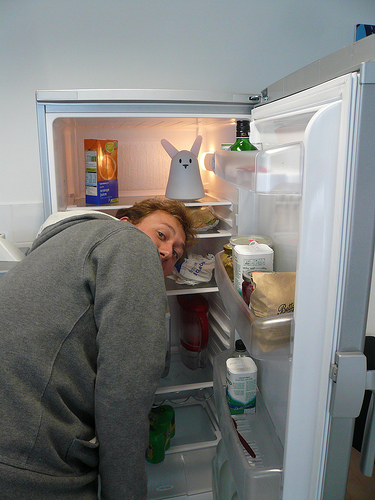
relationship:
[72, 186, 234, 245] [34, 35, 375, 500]
shelf in fridge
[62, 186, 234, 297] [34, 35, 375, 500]
shelf in fridge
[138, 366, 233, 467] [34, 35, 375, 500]
shelf in fridge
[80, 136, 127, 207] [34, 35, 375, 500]
orange juice inside fridge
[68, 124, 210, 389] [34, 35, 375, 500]
back wall inside fridge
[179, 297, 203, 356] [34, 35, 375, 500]
pitcher inside fridge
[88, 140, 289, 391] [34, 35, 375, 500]
items are on fridge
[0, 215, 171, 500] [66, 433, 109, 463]
jacket has a pocket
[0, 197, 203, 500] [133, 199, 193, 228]
boy has hair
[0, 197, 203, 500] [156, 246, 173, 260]
boy has a nose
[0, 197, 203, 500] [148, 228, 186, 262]
boy has eyes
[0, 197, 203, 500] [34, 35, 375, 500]
boy in fridge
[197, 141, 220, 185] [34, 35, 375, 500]
light on inside fridge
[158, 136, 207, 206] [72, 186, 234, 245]
rabbit on shelf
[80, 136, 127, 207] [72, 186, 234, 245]
orange juice on shelf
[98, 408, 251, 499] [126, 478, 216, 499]
drawer on bottom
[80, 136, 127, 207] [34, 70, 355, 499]
orange juice on fridge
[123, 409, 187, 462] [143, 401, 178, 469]
pack of soda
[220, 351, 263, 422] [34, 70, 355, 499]
milk inside fridge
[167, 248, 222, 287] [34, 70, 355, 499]
cookies are inside fridge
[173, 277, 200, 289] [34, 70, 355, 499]
spoon inside fridge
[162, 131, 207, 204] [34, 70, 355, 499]
cat inside fridge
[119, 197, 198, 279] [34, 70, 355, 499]
head inside fridge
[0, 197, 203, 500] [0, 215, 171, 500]
boy wearing a grey sweater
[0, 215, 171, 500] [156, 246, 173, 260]
person has a nose